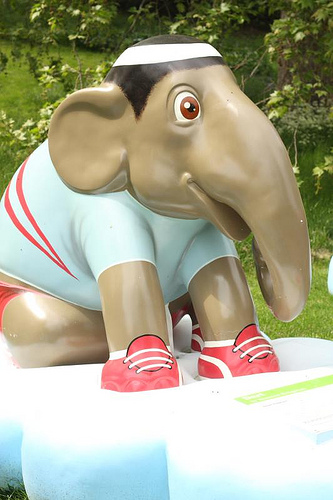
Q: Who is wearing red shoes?
A: The elephant.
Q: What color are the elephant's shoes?
A: Red.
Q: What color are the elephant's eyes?
A: Brown.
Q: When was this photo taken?
A: Outside, during the daytime.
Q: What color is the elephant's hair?
A: Black.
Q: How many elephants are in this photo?
A: One.